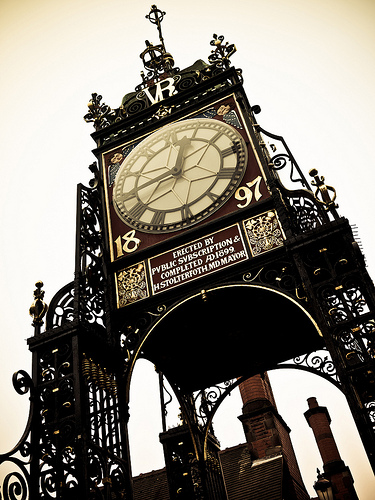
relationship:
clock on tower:
[101, 97, 280, 243] [36, 48, 373, 486]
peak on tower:
[127, 300, 351, 482] [36, 48, 373, 486]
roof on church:
[132, 445, 292, 496] [139, 358, 375, 498]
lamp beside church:
[311, 466, 334, 498] [139, 358, 375, 498]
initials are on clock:
[142, 79, 180, 101] [101, 97, 280, 243]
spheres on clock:
[129, 1, 179, 70] [101, 97, 280, 243]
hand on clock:
[174, 138, 194, 172] [101, 97, 280, 243]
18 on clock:
[115, 229, 142, 256] [101, 97, 280, 243]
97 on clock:
[234, 175, 264, 205] [101, 97, 280, 243]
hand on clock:
[126, 173, 176, 196] [101, 97, 280, 243]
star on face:
[139, 147, 222, 207] [121, 123, 227, 209]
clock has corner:
[101, 97, 280, 243] [218, 84, 245, 113]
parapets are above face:
[136, 1, 179, 67] [121, 123, 227, 209]